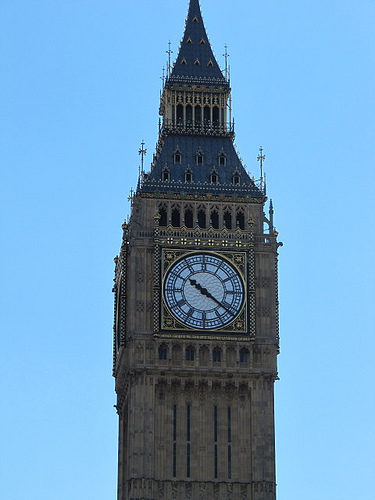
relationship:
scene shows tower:
[3, 2, 371, 499] [122, 2, 280, 500]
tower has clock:
[122, 2, 280, 500] [163, 252, 247, 333]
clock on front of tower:
[163, 252, 247, 333] [122, 2, 280, 500]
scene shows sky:
[3, 2, 371, 499] [6, 6, 122, 133]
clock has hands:
[163, 252, 247, 333] [186, 278, 233, 319]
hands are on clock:
[186, 278, 233, 319] [163, 252, 247, 333]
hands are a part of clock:
[186, 278, 233, 319] [163, 252, 247, 333]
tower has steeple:
[122, 2, 280, 500] [145, 0, 263, 189]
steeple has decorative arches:
[155, 1, 243, 140] [169, 97, 227, 127]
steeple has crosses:
[155, 1, 243, 140] [159, 41, 233, 76]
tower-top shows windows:
[125, 199, 294, 338] [158, 201, 253, 231]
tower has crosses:
[122, 2, 280, 500] [159, 41, 233, 76]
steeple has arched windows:
[155, 1, 243, 140] [169, 97, 227, 127]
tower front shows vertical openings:
[122, 2, 280, 500] [168, 399, 238, 483]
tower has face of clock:
[122, 2, 280, 500] [163, 252, 247, 333]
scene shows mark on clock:
[3, 2, 371, 499] [163, 252, 247, 333]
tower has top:
[122, 2, 280, 500] [173, 2, 228, 83]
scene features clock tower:
[3, 2, 371, 499] [122, 2, 280, 500]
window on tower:
[155, 201, 169, 230] [122, 2, 280, 500]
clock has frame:
[163, 252, 247, 333] [155, 242, 252, 344]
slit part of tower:
[210, 400, 221, 449] [122, 2, 280, 500]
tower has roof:
[122, 2, 280, 500] [173, 2, 228, 83]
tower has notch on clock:
[122, 2, 280, 500] [163, 252, 247, 333]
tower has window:
[122, 2, 280, 500] [155, 201, 169, 230]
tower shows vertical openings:
[122, 2, 280, 500] [168, 399, 238, 483]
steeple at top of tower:
[155, 1, 243, 140] [122, 2, 280, 500]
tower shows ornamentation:
[122, 2, 280, 500] [129, 48, 274, 244]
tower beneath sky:
[122, 2, 280, 500] [6, 6, 122, 133]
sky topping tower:
[6, 6, 122, 133] [122, 2, 280, 500]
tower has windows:
[122, 2, 280, 500] [158, 201, 253, 231]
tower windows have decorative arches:
[122, 2, 280, 500] [169, 97, 227, 127]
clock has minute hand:
[163, 252, 247, 333] [208, 296, 244, 322]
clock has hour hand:
[163, 252, 247, 333] [188, 277, 207, 296]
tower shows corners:
[122, 2, 280, 500] [95, 229, 154, 360]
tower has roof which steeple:
[122, 2, 280, 500] [155, 1, 243, 140]